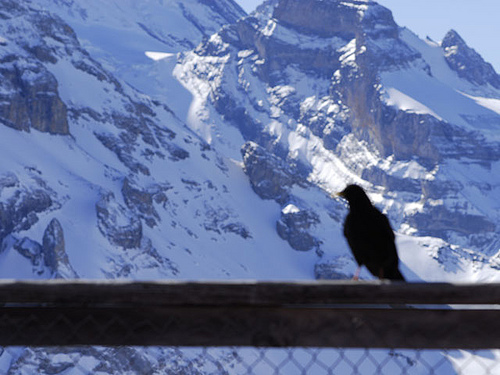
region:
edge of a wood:
[377, 310, 425, 330]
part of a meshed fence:
[263, 330, 299, 362]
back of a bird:
[353, 215, 383, 257]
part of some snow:
[223, 241, 255, 266]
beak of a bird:
[329, 178, 345, 205]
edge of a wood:
[185, 266, 239, 309]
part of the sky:
[424, 4, 446, 24]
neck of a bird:
[353, 201, 378, 220]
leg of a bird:
[348, 262, 371, 284]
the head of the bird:
[326, 180, 366, 205]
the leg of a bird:
[346, 262, 363, 282]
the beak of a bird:
[326, 187, 345, 201]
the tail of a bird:
[378, 265, 418, 282]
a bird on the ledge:
[331, 180, 416, 283]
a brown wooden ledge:
[0, 276, 499, 349]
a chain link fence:
[0, 282, 499, 373]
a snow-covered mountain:
[1, 0, 499, 374]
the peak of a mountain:
[441, 22, 466, 46]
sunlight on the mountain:
[143, 47, 176, 62]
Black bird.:
[330, 168, 423, 291]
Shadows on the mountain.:
[9, 46, 200, 237]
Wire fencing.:
[6, 306, 468, 368]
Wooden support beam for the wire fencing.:
[5, 266, 492, 361]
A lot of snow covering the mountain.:
[30, 80, 286, 250]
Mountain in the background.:
[10, 0, 460, 187]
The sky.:
[400, 0, 495, 45]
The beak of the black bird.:
[330, 185, 345, 200]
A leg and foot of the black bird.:
[345, 265, 365, 281]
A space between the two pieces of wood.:
[275, 297, 495, 312]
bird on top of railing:
[302, 167, 422, 295]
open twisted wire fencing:
[80, 337, 442, 372]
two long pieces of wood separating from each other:
[43, 275, 476, 335]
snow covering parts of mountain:
[31, 45, 321, 210]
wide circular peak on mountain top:
[205, 0, 477, 81]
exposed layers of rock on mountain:
[252, 45, 427, 181]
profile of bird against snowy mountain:
[306, 166, 411, 286]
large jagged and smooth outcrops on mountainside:
[11, 37, 162, 259]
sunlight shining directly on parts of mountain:
[160, 36, 465, 176]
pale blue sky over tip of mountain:
[392, 2, 493, 37]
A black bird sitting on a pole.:
[327, 183, 404, 284]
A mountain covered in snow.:
[258, 2, 375, 159]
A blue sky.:
[398, 2, 498, 25]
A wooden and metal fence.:
[2, 280, 499, 374]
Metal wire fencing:
[0, 315, 499, 374]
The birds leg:
[345, 265, 366, 282]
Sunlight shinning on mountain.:
[177, 53, 236, 81]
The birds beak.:
[330, 191, 344, 198]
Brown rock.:
[349, 105, 375, 124]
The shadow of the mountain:
[125, 41, 197, 121]